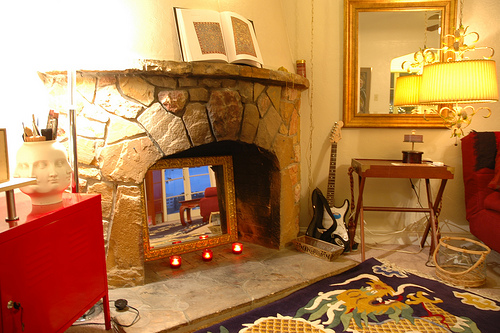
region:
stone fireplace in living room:
[39, 57, 356, 331]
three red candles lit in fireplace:
[170, 240, 244, 265]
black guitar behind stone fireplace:
[306, 118, 351, 252]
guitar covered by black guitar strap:
[315, 186, 346, 252]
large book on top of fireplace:
[172, 5, 264, 66]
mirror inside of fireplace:
[144, 154, 239, 260]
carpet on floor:
[188, 255, 498, 331]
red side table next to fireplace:
[0, 191, 112, 331]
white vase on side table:
[13, 132, 73, 204]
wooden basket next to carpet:
[430, 235, 491, 288]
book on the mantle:
[155, 10, 339, 106]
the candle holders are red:
[99, 137, 295, 298]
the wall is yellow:
[306, 17, 333, 94]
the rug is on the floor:
[328, 234, 438, 331]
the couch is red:
[460, 127, 498, 262]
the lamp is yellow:
[403, 28, 499, 162]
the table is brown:
[323, 145, 468, 263]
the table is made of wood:
[342, 135, 451, 271]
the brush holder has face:
[13, 126, 88, 235]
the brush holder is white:
[2, 110, 106, 215]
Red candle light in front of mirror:
[167, 255, 182, 267]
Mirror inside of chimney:
[137, 153, 236, 256]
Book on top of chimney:
[175, 5, 263, 67]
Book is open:
[171, 7, 263, 69]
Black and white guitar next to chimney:
[307, 122, 351, 254]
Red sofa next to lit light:
[461, 125, 497, 255]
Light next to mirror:
[420, 0, 495, 140]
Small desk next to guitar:
[350, 158, 452, 268]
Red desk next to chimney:
[0, 192, 111, 332]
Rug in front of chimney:
[137, 254, 497, 331]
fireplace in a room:
[25, 41, 367, 331]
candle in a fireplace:
[160, 247, 187, 276]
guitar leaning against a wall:
[297, 113, 358, 259]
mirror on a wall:
[337, 0, 462, 133]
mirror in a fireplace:
[129, 145, 244, 267]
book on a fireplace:
[162, 0, 272, 75]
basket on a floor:
[428, 227, 495, 297]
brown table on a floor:
[343, 150, 454, 260]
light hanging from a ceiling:
[414, 2, 496, 153]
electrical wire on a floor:
[66, 292, 143, 332]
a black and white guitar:
[303, 110, 378, 277]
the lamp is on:
[384, 21, 496, 161]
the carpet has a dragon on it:
[160, 251, 494, 331]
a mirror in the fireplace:
[114, 142, 259, 282]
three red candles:
[144, 227, 279, 298]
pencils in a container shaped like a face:
[9, 106, 96, 220]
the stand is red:
[1, 155, 144, 332]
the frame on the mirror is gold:
[329, 1, 491, 153]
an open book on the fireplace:
[145, 1, 278, 76]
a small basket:
[416, 225, 496, 307]